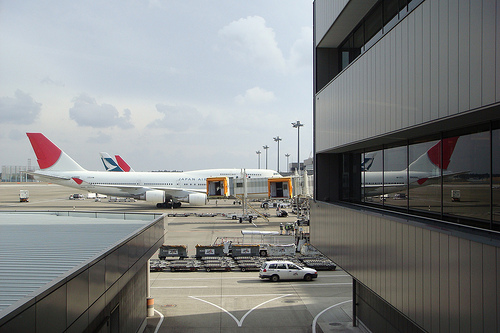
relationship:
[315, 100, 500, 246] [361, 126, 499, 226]
window has reflection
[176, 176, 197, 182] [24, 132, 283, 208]
japan on plane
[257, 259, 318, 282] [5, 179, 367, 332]
vehicle on ground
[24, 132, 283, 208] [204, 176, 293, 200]
airplane has ramp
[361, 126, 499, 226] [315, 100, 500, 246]
reflection in window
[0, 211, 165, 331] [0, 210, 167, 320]
building has roof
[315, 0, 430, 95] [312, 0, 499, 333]
windows on building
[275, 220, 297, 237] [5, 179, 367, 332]
workers on ground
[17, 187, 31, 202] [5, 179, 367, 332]
equipment on ground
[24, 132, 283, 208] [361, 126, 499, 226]
plane has reflection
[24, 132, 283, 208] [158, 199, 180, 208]
airplane has wheels